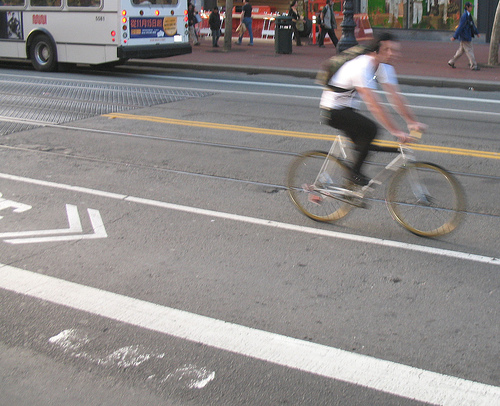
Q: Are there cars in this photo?
A: No, there are no cars.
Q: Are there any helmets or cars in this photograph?
A: No, there are no cars or helmets.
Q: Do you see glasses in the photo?
A: No, there are no glasses.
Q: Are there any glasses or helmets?
A: No, there are no glasses or helmets.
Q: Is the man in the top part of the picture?
A: Yes, the man is in the top of the image.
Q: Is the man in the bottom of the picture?
A: No, the man is in the top of the image.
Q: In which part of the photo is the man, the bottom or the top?
A: The man is in the top of the image.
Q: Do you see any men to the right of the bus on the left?
A: Yes, there is a man to the right of the bus.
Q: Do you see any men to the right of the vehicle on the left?
A: Yes, there is a man to the right of the bus.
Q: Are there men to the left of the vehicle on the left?
A: No, the man is to the right of the bus.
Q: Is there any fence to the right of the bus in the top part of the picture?
A: No, there is a man to the right of the bus.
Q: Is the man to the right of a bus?
A: Yes, the man is to the right of a bus.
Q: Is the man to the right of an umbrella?
A: No, the man is to the right of a bus.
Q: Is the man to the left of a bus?
A: No, the man is to the right of a bus.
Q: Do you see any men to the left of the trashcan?
A: Yes, there is a man to the left of the trashcan.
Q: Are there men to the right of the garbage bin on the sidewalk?
A: No, the man is to the left of the garbage can.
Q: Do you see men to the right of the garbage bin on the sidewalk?
A: No, the man is to the left of the garbage can.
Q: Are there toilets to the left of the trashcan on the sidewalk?
A: No, there is a man to the left of the trash can.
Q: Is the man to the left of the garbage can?
A: Yes, the man is to the left of the garbage can.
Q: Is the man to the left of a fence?
A: No, the man is to the left of the garbage can.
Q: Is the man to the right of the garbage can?
A: No, the man is to the left of the garbage can.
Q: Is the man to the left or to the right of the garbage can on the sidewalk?
A: The man is to the left of the trash can.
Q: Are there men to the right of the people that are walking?
A: Yes, there is a man to the right of the people.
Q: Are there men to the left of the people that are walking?
A: No, the man is to the right of the people.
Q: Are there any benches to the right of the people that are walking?
A: No, there is a man to the right of the people.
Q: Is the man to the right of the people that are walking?
A: Yes, the man is to the right of the people.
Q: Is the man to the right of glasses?
A: No, the man is to the right of the people.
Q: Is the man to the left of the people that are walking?
A: No, the man is to the right of the people.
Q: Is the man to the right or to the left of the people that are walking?
A: The man is to the right of the people.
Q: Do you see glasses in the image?
A: No, there are no glasses.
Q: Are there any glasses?
A: No, there are no glasses.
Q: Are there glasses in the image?
A: No, there are no glasses.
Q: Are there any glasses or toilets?
A: No, there are no glasses or toilets.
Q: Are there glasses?
A: No, there are no glasses.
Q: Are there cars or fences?
A: No, there are no cars or fences.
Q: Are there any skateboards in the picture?
A: No, there are no skateboards.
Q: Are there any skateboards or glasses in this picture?
A: No, there are no skateboards or glasses.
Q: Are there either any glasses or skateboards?
A: No, there are no skateboards or glasses.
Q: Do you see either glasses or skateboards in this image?
A: No, there are no skateboards or glasses.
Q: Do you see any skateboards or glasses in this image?
A: No, there are no skateboards or glasses.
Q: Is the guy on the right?
A: Yes, the guy is on the right of the image.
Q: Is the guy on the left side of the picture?
A: No, the guy is on the right of the image.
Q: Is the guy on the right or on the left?
A: The guy is on the right of the image.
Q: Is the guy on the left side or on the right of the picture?
A: The guy is on the right of the image.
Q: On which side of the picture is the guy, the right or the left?
A: The guy is on the right of the image.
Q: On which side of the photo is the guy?
A: The guy is on the right of the image.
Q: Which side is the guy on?
A: The guy is on the right of the image.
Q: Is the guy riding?
A: Yes, the guy is riding.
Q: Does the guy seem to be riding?
A: Yes, the guy is riding.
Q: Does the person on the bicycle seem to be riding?
A: Yes, the guy is riding.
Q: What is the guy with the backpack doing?
A: The guy is riding.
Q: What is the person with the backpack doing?
A: The guy is riding.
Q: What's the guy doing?
A: The guy is riding.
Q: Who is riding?
A: The guy is riding.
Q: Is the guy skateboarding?
A: No, the guy is riding.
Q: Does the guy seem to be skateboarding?
A: No, the guy is riding.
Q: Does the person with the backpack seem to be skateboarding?
A: No, the guy is riding.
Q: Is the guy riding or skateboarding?
A: The guy is riding.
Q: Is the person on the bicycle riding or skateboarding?
A: The guy is riding.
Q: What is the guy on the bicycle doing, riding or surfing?
A: The guy is riding.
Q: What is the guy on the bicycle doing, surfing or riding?
A: The guy is riding.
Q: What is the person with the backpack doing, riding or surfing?
A: The guy is riding.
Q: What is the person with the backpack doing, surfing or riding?
A: The guy is riding.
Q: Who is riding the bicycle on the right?
A: The guy is riding the bicycle.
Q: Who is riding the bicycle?
A: The guy is riding the bicycle.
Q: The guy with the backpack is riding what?
A: The guy is riding the bicycle.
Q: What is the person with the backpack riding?
A: The guy is riding the bicycle.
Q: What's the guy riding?
A: The guy is riding the bicycle.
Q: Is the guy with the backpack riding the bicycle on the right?
A: Yes, the guy is riding the bicycle.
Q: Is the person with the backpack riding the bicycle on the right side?
A: Yes, the guy is riding the bicycle.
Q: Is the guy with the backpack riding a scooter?
A: No, the guy is riding the bicycle.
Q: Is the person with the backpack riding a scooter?
A: No, the guy is riding the bicycle.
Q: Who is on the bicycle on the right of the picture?
A: The guy is on the bicycle.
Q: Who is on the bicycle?
A: The guy is on the bicycle.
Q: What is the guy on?
A: The guy is on the bicycle.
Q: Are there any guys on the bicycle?
A: Yes, there is a guy on the bicycle.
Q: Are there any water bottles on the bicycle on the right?
A: No, there is a guy on the bicycle.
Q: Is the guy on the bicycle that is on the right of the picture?
A: Yes, the guy is on the bicycle.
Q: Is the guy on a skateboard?
A: No, the guy is on the bicycle.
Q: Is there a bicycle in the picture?
A: Yes, there is a bicycle.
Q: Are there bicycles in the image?
A: Yes, there is a bicycle.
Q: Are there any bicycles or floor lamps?
A: Yes, there is a bicycle.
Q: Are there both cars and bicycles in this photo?
A: No, there is a bicycle but no cars.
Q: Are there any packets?
A: No, there are no packets.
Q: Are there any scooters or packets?
A: No, there are no packets or scooters.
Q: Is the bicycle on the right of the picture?
A: Yes, the bicycle is on the right of the image.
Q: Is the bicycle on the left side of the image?
A: No, the bicycle is on the right of the image.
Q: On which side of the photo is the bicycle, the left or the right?
A: The bicycle is on the right of the image.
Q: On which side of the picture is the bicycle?
A: The bicycle is on the right of the image.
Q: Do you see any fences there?
A: No, there are no fences.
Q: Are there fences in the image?
A: No, there are no fences.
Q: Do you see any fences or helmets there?
A: No, there are no fences or helmets.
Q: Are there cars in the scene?
A: No, there are no cars.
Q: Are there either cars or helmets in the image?
A: No, there are no cars or helmets.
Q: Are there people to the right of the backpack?
A: Yes, there is a person to the right of the backpack.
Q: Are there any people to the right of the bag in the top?
A: Yes, there is a person to the right of the backpack.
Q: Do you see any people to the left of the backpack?
A: No, the person is to the right of the backpack.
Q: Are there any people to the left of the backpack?
A: No, the person is to the right of the backpack.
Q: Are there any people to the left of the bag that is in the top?
A: No, the person is to the right of the backpack.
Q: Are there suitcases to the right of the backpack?
A: No, there is a person to the right of the backpack.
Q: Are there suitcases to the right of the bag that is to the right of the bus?
A: No, there is a person to the right of the backpack.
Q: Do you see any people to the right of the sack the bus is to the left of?
A: Yes, there is a person to the right of the sack.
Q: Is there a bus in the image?
A: Yes, there is a bus.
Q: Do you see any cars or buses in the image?
A: Yes, there is a bus.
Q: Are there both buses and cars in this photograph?
A: No, there is a bus but no cars.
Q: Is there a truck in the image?
A: No, there are no trucks.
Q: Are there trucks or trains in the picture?
A: No, there are no trucks or trains.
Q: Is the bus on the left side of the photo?
A: Yes, the bus is on the left of the image.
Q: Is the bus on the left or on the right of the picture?
A: The bus is on the left of the image.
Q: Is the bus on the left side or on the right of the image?
A: The bus is on the left of the image.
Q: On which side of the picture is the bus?
A: The bus is on the left of the image.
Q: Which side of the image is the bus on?
A: The bus is on the left of the image.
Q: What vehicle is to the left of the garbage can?
A: The vehicle is a bus.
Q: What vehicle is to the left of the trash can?
A: The vehicle is a bus.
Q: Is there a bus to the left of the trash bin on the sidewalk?
A: Yes, there is a bus to the left of the garbage can.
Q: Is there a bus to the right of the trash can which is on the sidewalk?
A: No, the bus is to the left of the trashcan.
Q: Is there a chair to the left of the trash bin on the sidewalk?
A: No, there is a bus to the left of the trash can.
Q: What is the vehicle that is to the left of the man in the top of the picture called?
A: The vehicle is a bus.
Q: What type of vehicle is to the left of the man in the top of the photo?
A: The vehicle is a bus.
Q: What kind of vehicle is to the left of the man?
A: The vehicle is a bus.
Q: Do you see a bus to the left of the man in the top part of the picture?
A: Yes, there is a bus to the left of the man.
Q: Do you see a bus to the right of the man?
A: No, the bus is to the left of the man.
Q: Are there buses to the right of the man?
A: No, the bus is to the left of the man.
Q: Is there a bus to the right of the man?
A: No, the bus is to the left of the man.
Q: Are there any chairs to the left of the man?
A: No, there is a bus to the left of the man.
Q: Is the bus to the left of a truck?
A: No, the bus is to the left of the man.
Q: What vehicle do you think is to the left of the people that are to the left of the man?
A: The vehicle is a bus.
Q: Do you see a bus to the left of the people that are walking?
A: Yes, there is a bus to the left of the people.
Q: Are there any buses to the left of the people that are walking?
A: Yes, there is a bus to the left of the people.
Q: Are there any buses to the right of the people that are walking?
A: No, the bus is to the left of the people.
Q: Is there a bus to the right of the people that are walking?
A: No, the bus is to the left of the people.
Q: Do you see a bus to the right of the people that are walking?
A: No, the bus is to the left of the people.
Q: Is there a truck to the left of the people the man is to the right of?
A: No, there is a bus to the left of the people.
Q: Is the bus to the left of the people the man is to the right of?
A: Yes, the bus is to the left of the people.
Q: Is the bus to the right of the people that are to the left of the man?
A: No, the bus is to the left of the people.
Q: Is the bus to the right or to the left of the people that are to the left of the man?
A: The bus is to the left of the people.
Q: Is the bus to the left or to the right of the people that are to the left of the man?
A: The bus is to the left of the people.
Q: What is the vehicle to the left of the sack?
A: The vehicle is a bus.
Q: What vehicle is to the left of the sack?
A: The vehicle is a bus.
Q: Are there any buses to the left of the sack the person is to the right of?
A: Yes, there is a bus to the left of the sack.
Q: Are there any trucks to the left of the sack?
A: No, there is a bus to the left of the sack.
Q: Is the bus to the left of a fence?
A: No, the bus is to the left of a sack.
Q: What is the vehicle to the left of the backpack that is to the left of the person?
A: The vehicle is a bus.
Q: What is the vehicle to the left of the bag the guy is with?
A: The vehicle is a bus.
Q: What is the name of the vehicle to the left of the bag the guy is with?
A: The vehicle is a bus.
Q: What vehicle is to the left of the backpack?
A: The vehicle is a bus.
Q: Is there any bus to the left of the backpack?
A: Yes, there is a bus to the left of the backpack.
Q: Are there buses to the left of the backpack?
A: Yes, there is a bus to the left of the backpack.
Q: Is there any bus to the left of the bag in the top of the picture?
A: Yes, there is a bus to the left of the backpack.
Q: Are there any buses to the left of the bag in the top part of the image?
A: Yes, there is a bus to the left of the backpack.